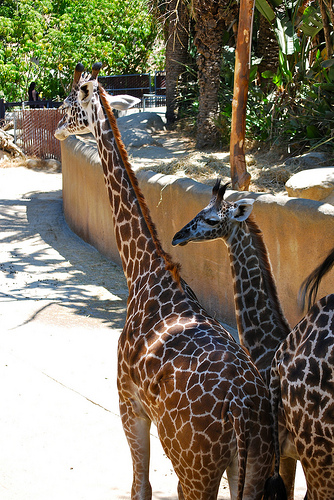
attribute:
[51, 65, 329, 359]
giraffes — spotted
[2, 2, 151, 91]
trees — tall, leafy, green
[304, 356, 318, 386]
spot — brown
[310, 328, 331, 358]
spot — brown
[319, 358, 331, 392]
spot — brown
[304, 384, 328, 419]
spot — brown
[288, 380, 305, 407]
spot — brown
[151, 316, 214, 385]
spots — brown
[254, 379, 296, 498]
tail — giraffe's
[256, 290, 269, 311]
spot — brown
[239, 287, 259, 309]
spot — brown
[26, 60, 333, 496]
giraffe — tall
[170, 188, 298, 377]
giraffe — tall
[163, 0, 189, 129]
tree trunk — palm tree's, brown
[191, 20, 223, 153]
trunk — brown, palm tree's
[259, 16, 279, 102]
trunk — brown, palm tree's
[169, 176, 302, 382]
giraffe — baby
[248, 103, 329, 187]
rocks — large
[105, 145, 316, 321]
wall — concrete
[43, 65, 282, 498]
giraffe — tall, tan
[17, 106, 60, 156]
fence — metal, chain-link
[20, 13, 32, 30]
leaves — green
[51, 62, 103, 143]
head — giraffe's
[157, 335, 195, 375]
spots — brown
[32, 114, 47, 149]
lattice — brown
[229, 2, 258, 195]
trunk — brown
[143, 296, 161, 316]
spot — brown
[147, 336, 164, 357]
spot — brown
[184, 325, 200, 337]
spot — brown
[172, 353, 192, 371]
spot — brown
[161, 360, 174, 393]
spot — brown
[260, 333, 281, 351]
spot — brown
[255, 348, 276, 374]
spot — brown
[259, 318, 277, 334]
spot — brown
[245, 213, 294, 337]
mane — red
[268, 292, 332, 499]
giraffe — tan